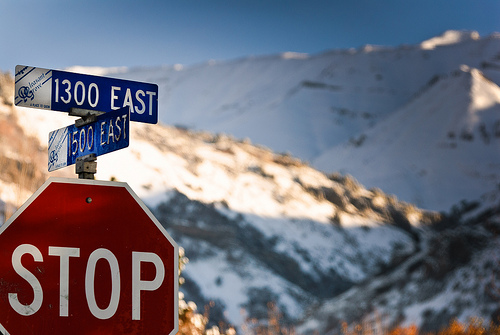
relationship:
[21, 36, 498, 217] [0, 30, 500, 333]
snow on mountains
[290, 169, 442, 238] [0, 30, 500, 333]
rocks on mountains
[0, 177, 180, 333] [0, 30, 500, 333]
stop sign near mountains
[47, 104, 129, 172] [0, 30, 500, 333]
street sign near mountains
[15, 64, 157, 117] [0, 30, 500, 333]
street sign near mountains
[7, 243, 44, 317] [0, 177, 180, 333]
letter on stop sign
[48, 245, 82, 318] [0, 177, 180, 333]
letter on stop sign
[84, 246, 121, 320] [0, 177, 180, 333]
letter on stop sign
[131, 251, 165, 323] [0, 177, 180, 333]
letter on stop sign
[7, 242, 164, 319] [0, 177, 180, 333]
stop on stop sign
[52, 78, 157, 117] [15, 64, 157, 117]
letters on street sign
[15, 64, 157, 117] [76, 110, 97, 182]
street sign on top of pole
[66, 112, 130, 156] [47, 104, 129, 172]
letters on street sign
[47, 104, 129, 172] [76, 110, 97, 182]
street sign on pole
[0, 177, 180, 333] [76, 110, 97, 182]
stop sign on pole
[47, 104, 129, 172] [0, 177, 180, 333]
street sign over stop sign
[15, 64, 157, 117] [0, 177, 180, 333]
street sign over stop sign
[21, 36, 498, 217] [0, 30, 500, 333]
snow covering mountains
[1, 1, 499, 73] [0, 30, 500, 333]
sky over mountains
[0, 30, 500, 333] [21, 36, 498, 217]
mountains covered by snow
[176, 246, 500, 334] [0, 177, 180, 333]
leaves behind stop sign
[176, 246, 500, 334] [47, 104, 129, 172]
leaves behind street sign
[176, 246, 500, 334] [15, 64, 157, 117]
leaves behind street sign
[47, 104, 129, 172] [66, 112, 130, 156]
street sign with letters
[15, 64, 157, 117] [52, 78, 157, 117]
street sign with letters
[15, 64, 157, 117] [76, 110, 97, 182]
street sign on pole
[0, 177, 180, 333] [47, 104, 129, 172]
stop sign under street sign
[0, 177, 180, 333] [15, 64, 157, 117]
stop sign under street sign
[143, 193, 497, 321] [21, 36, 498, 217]
shadow on snow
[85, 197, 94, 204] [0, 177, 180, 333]
bolt in stop sign